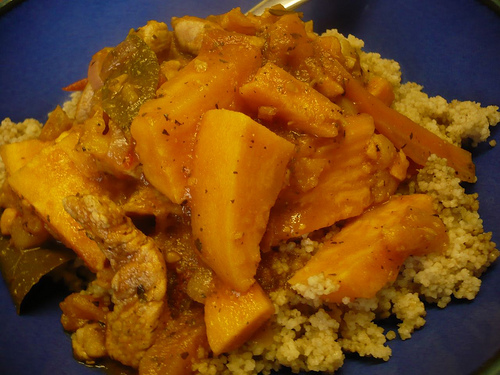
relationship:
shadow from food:
[22, 281, 72, 319] [74, 223, 211, 375]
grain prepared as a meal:
[225, 158, 248, 187] [30, 10, 484, 365]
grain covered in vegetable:
[225, 158, 248, 187] [184, 109, 284, 296]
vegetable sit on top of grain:
[184, 109, 284, 296] [252, 2, 469, 128]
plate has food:
[0, 0, 500, 375] [42, 22, 456, 346]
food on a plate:
[0, 15, 452, 345] [2, 3, 482, 373]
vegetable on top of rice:
[184, 109, 284, 296] [201, 27, 484, 372]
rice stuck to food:
[285, 273, 342, 306] [291, 189, 450, 306]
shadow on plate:
[22, 281, 72, 319] [2, 3, 482, 373]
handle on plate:
[242, 0, 313, 14] [2, 3, 482, 373]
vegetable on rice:
[184, 109, 284, 296] [201, 27, 484, 372]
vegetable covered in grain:
[184, 109, 284, 296] [219, 14, 484, 370]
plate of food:
[2, 3, 482, 373] [0, 0, 500, 375]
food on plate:
[0, 0, 500, 375] [2, 3, 482, 373]